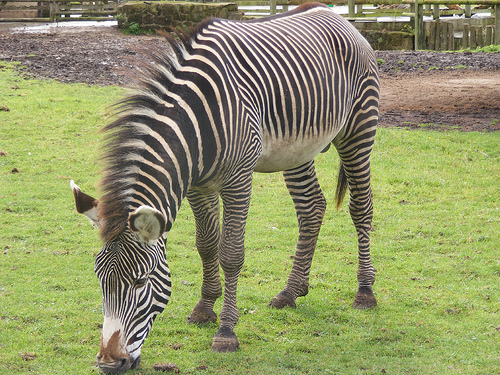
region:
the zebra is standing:
[91, 17, 401, 371]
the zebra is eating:
[57, 2, 417, 363]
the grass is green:
[411, 199, 465, 284]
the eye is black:
[111, 257, 161, 294]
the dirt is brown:
[387, 59, 476, 104]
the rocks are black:
[43, 40, 112, 96]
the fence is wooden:
[396, 22, 459, 42]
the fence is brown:
[408, 8, 454, 45]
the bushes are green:
[126, 5, 178, 32]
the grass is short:
[412, 236, 452, 331]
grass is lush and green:
[8, 100, 491, 350]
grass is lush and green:
[53, 187, 408, 367]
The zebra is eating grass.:
[17, 172, 227, 373]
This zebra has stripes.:
[98, 42, 420, 373]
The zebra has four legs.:
[45, 42, 415, 372]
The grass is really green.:
[404, 20, 480, 350]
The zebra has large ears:
[60, 187, 185, 373]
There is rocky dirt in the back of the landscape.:
[2, 21, 496, 124]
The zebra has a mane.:
[80, 17, 203, 354]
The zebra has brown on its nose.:
[90, 252, 171, 371]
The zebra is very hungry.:
[27, 47, 209, 369]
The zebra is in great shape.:
[15, 10, 495, 333]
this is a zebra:
[76, 5, 379, 374]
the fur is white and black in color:
[139, 165, 178, 194]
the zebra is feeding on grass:
[71, 188, 173, 373]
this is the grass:
[401, 147, 494, 351]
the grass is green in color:
[396, 144, 474, 181]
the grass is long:
[380, 136, 474, 185]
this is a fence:
[417, 9, 494, 49]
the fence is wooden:
[427, 21, 485, 46]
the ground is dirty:
[28, 43, 103, 68]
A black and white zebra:
[74, 1, 399, 371]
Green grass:
[400, 229, 498, 348]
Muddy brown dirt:
[387, 52, 498, 129]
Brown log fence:
[410, 4, 498, 49]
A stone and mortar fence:
[105, 2, 230, 36]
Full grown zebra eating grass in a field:
[89, 1, 425, 373]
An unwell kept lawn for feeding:
[0, 70, 90, 372]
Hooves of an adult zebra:
[164, 284, 427, 366]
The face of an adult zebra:
[55, 176, 192, 373]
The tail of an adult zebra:
[310, 137, 381, 212]